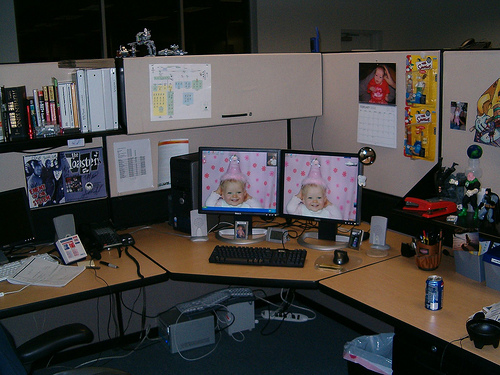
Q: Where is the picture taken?
A: Cubicle.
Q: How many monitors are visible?
A: 2.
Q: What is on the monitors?
A: Baby.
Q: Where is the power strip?
A: Under the desk.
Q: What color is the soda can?
A: Blue.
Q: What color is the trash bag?
A: White.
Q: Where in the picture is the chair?
A: Left.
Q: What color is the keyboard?
A: Black.